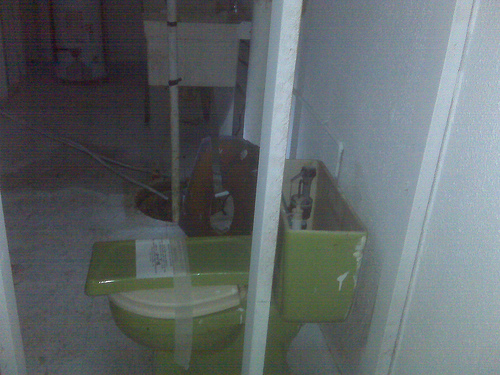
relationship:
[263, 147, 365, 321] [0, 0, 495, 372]
green tank of bathroom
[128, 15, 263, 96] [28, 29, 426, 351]
sink in basement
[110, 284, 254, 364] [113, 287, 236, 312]
toilet bowl with cover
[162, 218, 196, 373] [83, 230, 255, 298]
strap holding tank cover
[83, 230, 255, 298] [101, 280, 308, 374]
tank cover held to toilet bowl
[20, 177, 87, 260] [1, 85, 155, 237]
carpet on floor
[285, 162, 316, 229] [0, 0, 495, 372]
inter-workings of bathroom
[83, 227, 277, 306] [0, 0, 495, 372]
toilet lid strapped to bathroom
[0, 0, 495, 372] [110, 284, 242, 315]
bathroom with seat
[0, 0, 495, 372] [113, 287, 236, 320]
bathroom with cover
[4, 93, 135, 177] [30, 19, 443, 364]
cables in bathroom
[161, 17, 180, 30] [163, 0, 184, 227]
black tape around pvc pipe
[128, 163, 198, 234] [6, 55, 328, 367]
hole in floor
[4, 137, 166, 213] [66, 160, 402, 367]
water spot on floor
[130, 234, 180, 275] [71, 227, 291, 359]
sign on top of toilet